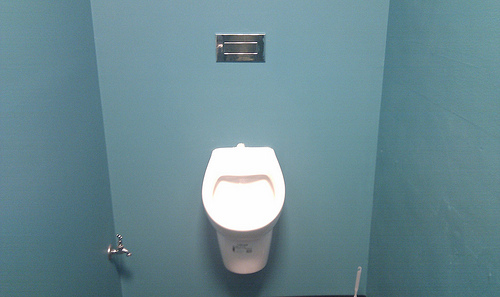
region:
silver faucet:
[90, 210, 168, 267]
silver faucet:
[90, 231, 150, 288]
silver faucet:
[107, 235, 172, 289]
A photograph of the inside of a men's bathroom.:
[2, 5, 487, 290]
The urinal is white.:
[170, 126, 310, 286]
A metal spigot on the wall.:
[101, 216, 137, 266]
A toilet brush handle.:
[336, 245, 376, 291]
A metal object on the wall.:
[207, 25, 268, 75]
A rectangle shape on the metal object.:
[217, 36, 257, 51]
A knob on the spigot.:
[111, 215, 123, 240]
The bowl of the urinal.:
[211, 165, 266, 215]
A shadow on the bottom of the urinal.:
[215, 225, 275, 235]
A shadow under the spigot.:
[105, 252, 135, 277]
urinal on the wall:
[191, 117, 306, 280]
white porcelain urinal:
[189, 130, 306, 285]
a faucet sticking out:
[100, 225, 149, 278]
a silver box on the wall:
[211, 27, 284, 66]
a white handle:
[345, 249, 377, 295]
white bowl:
[205, 167, 277, 222]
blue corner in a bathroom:
[335, 83, 429, 175]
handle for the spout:
[112, 231, 130, 244]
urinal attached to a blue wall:
[124, 125, 369, 285]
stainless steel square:
[201, 17, 291, 79]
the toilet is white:
[254, 160, 264, 185]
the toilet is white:
[255, 171, 257, 176]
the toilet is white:
[248, 157, 259, 184]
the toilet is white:
[257, 177, 273, 206]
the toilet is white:
[252, 185, 261, 204]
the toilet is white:
[242, 186, 251, 202]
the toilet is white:
[256, 173, 263, 193]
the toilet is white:
[254, 191, 264, 206]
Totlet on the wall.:
[194, 131, 291, 272]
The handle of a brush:
[354, 259, 362, 296]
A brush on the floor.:
[348, 265, 370, 296]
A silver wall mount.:
[212, 30, 269, 67]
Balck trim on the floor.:
[255, 291, 356, 296]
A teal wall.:
[289, 37, 349, 214]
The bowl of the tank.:
[218, 172, 273, 215]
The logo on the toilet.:
[229, 235, 257, 255]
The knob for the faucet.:
[113, 230, 128, 243]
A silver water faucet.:
[96, 226, 138, 262]